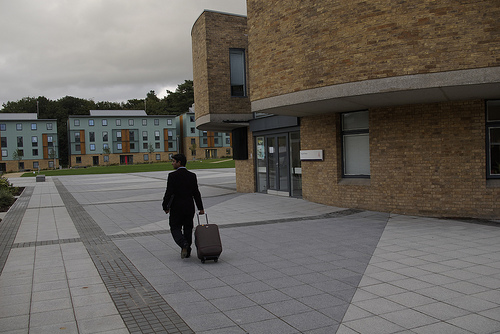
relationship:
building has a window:
[247, 2, 499, 223] [338, 111, 373, 180]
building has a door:
[247, 2, 499, 223] [265, 131, 292, 196]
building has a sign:
[247, 2, 499, 223] [299, 148, 324, 162]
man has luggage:
[162, 153, 206, 257] [196, 211, 221, 258]